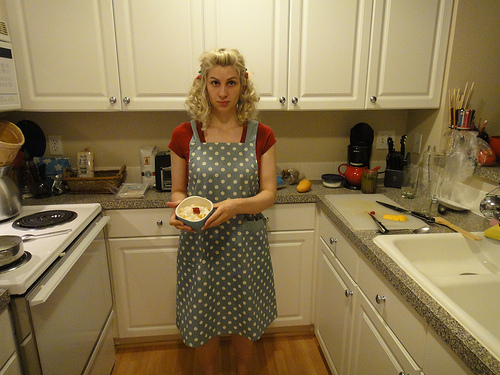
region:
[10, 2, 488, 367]
Photo takes place in a kitchen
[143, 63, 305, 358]
Woman wearing an apron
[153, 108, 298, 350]
Polka dotted apron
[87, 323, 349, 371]
The floor is wooden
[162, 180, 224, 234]
Bowl in the woman's hands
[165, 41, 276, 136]
The woman is blond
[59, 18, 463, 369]
The cabinets are white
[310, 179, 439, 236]
Cutting board on the counter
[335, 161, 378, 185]
Red tea pot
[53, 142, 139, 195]
Basket on the counter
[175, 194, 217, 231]
the bowl in the woman's hands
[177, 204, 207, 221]
the food in the bowl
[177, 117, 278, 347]
the apron on the woman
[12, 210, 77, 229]
the burner on the stove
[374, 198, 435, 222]
the large knife on the cutting board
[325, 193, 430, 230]
the cutting board on the counter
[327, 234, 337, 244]
the knob on the drawer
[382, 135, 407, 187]
the knife block in the corner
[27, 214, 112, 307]
the handle on the oven door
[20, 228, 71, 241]
the spoon on the stove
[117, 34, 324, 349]
woman standing in the kitchen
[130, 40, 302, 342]
woman wearing a polka dot dress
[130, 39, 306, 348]
the dress is grey and white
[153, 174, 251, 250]
woman is holding a bowl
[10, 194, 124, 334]
the stove is white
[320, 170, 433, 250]
a cutting board on the counter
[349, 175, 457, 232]
the counter is grey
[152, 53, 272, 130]
the woman`s hair is blonde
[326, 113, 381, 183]
a coffee maker in the background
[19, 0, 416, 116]
the cabinets are white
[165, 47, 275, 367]
woman is wearing polka dot apron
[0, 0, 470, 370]
cabinets are painted white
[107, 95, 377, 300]
metal knobs on kitchen cabinets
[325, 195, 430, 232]
large white cutting board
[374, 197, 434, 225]
large knife on cutting board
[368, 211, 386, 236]
small knife on cutting board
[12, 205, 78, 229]
black burner on stove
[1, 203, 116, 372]
white stove by person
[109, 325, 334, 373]
wooden floor under woman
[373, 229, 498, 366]
white dual basin sink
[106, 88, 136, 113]
Two knobs on cabinets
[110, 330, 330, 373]
A brown wooden floor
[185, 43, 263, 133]
Woman has blonde hair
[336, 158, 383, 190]
A red tea kettle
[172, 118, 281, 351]
White polka dots on an apron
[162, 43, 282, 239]
A woman is holding a bowl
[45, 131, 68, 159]
Electrical outlet on the wall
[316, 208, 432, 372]
Two white drawers next to each other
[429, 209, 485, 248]
A brown wooden spoon